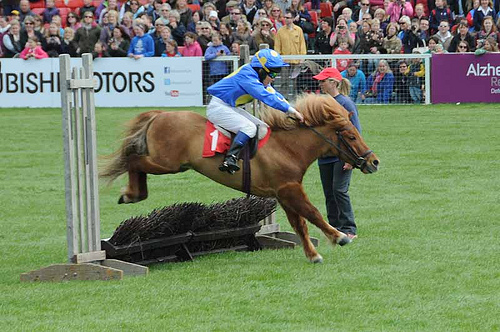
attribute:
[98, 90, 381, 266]
horse — brown, jumping, pony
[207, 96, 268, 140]
pants — white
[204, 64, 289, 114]
shirt — blue, yellow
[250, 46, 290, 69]
helmet — blue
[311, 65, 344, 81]
hat — red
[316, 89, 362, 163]
sweatshirt — blue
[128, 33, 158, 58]
shirt — blue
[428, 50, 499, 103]
sign — purple, white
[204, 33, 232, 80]
person — spectactor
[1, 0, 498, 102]
audience — crowd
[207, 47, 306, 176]
rider — jockey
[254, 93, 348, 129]
mane — flowing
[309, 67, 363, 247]
person — woman, standing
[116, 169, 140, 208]
leg — back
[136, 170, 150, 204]
leg — back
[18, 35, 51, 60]
person — girl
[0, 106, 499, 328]
ground — grass, green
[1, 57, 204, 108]
sign — white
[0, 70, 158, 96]
lettering — black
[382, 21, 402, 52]
spectator — watching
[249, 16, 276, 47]
spectator — watching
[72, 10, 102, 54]
spectator — watching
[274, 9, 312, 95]
man — standing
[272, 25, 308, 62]
shirt — yellow